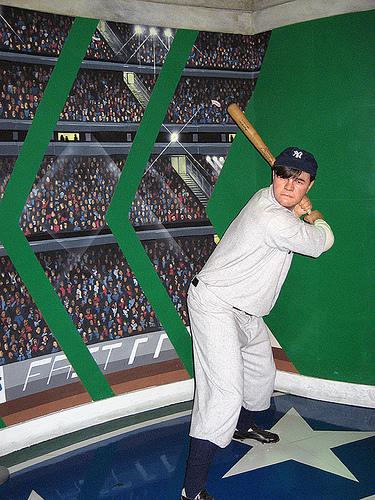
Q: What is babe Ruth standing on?
A: Star.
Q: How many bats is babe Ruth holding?
A: One.